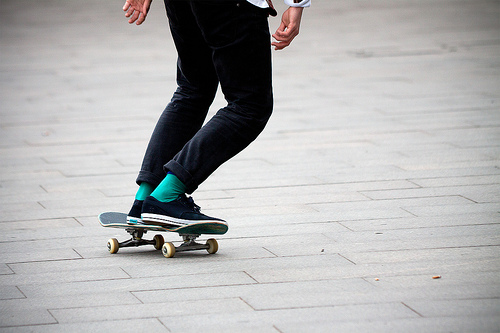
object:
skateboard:
[91, 206, 230, 258]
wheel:
[161, 243, 176, 258]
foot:
[126, 203, 226, 224]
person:
[121, 0, 312, 225]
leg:
[120, 0, 274, 224]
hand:
[272, 5, 305, 50]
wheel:
[207, 238, 219, 254]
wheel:
[107, 238, 120, 254]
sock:
[157, 171, 185, 202]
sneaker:
[138, 202, 205, 217]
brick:
[0, 248, 82, 265]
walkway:
[5, 1, 482, 332]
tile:
[28, 122, 106, 143]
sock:
[139, 182, 151, 195]